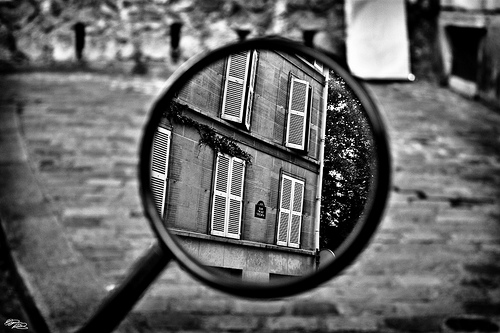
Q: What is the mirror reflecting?
A: An apartment building.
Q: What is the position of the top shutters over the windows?
A: Slightly open.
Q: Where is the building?
A: In the mirror.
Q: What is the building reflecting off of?
A: A mirror.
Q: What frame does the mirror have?
A: A round one.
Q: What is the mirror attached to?
A: A car.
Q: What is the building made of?
A: Bricks.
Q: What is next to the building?
A: Trees.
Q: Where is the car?
A: Next to a building.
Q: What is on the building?
A: Window shutters.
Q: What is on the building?
A: Wild vines.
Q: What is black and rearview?
A: A mirror.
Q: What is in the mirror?
A: A building reflection.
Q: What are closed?
A: The lower windows.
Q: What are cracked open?
A: The upper windows.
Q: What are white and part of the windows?
A: The shutters.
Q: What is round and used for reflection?
A: The mirror.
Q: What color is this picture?
A: Black and white.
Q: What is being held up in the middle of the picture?
A: Magnifying glass.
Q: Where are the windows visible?
A: In the middle.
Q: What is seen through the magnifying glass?
A: Windows.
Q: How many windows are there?
A: Five.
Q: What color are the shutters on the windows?
A: White.